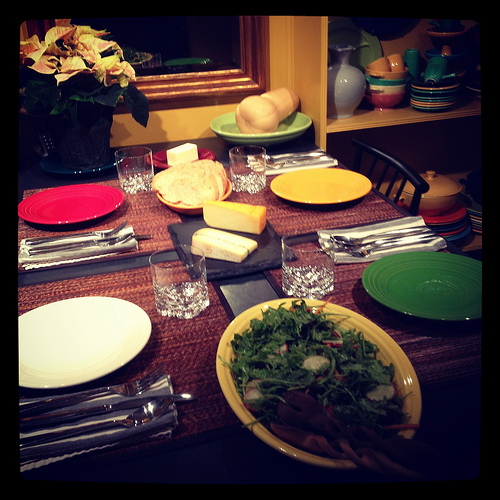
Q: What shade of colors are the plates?
A: Red, white, yellow and green.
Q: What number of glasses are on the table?
A: 4.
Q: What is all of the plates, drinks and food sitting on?
A: Table.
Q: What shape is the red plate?
A: Round.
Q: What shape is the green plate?
A: Round.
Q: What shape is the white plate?
A: Round.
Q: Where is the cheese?
A: On a black plate.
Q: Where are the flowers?
A: In a vase.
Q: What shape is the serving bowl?
A: Oval.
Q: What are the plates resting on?
A: Placemats.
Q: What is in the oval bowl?
A: Salad.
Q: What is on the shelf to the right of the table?
A: Dishes.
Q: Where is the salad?
A: On a yellow platter.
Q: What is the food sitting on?
A: A table.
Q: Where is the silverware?
A: To the right of the plates.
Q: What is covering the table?
A: Placemats.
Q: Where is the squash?
A: By the window.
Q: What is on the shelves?
A: Pottery.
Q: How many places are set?
A: Four.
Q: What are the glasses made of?
A: Glass.